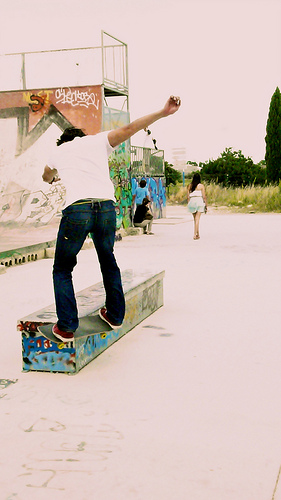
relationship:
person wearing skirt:
[188, 172, 207, 239] [186, 197, 206, 213]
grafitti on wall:
[108, 149, 166, 224] [1, 85, 163, 224]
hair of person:
[53, 124, 86, 147] [41, 93, 179, 341]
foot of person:
[98, 300, 123, 337] [41, 93, 179, 341]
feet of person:
[193, 233, 200, 240] [185, 171, 207, 238]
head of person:
[189, 170, 202, 183] [182, 170, 210, 242]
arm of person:
[103, 93, 180, 149] [41, 93, 179, 341]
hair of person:
[188, 171, 202, 193] [186, 172, 209, 241]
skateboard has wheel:
[26, 305, 160, 351] [54, 340, 64, 349]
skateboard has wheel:
[26, 305, 160, 351] [99, 332, 107, 339]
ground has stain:
[0, 204, 277, 493] [149, 321, 160, 329]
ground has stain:
[0, 204, 277, 493] [154, 332, 171, 337]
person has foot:
[54, 153, 93, 189] [52, 321, 75, 343]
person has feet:
[183, 182, 204, 225] [189, 227, 202, 240]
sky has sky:
[76, 44, 268, 116] [0, 0, 281, 87]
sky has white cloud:
[0, 0, 281, 87] [144, 33, 166, 51]